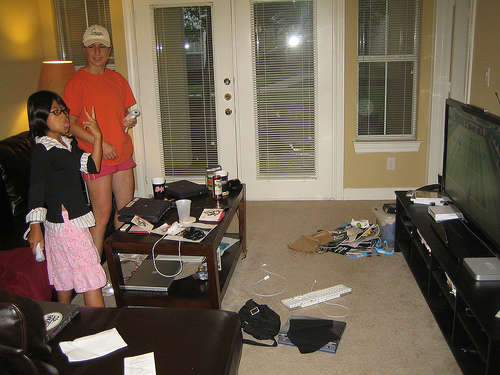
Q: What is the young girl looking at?
A: Wii tennis game.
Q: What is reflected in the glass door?
A: A flash.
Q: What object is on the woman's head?
A: Baseball cap.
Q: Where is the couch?
A: Behind the players.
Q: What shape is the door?
A: Rectangular.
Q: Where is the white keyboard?
A: On the floor.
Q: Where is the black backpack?
A: On the floor.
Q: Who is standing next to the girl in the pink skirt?
A: Woman in orange shirt.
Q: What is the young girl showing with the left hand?
A: Two.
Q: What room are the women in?
A: Living.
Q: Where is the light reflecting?
A: In the door.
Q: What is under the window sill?
A: Electrical outlet.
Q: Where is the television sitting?
A: ON the stand.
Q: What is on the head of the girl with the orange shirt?
A: Baseball cap.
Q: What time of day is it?
A: Night.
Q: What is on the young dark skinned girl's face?
A: Glasses.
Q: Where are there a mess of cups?
A: On the coffee table.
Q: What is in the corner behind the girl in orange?
A: A lamp.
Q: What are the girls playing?
A: Video game.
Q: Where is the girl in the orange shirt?
A: Near the lamp.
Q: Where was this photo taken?
A: In a living room.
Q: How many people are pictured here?
A: 2.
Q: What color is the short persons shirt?
A: Black.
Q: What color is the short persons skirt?
A: Pink.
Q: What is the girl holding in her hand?
A: Controller.